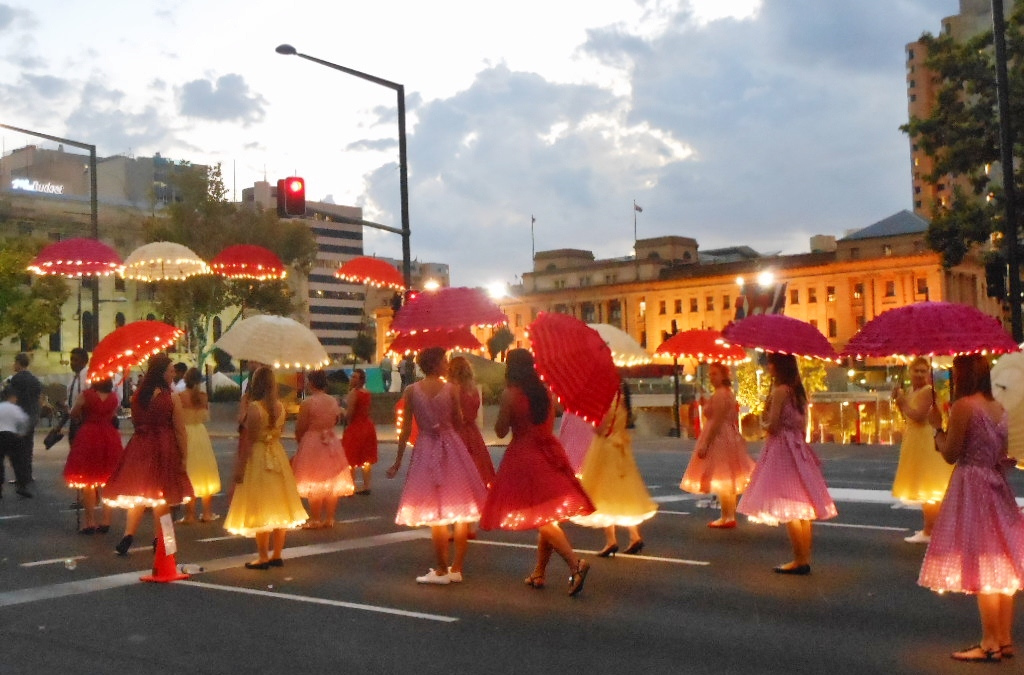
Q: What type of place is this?
A: It is a street.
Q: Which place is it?
A: It is a street.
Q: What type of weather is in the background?
A: It is cloudy.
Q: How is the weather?
A: It is cloudy.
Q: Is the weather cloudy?
A: Yes, it is cloudy.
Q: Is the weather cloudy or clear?
A: It is cloudy.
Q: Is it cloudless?
A: No, it is cloudy.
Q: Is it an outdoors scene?
A: Yes, it is outdoors.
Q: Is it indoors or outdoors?
A: It is outdoors.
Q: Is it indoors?
A: No, it is outdoors.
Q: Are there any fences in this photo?
A: No, there are no fences.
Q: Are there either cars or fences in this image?
A: No, there are no fences or cars.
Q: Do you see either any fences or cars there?
A: No, there are no fences or cars.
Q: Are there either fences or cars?
A: No, there are no fences or cars.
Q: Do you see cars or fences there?
A: No, there are no fences or cars.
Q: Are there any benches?
A: No, there are no benches.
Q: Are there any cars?
A: No, there are no cars.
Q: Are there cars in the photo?
A: No, there are no cars.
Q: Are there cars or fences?
A: No, there are no cars or fences.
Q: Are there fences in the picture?
A: No, there are no fences.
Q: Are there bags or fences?
A: No, there are no fences or bags.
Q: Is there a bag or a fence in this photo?
A: No, there are no fences or bags.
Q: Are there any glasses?
A: No, there are no glasses.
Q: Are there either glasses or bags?
A: No, there are no glasses or bags.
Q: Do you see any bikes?
A: No, there are no bikes.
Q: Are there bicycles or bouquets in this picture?
A: No, there are no bicycles or bouquets.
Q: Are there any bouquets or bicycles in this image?
A: No, there are no bicycles or bouquets.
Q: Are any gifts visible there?
A: No, there are no gifts.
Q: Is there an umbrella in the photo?
A: Yes, there is an umbrella.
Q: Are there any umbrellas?
A: Yes, there is an umbrella.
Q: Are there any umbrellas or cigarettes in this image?
A: Yes, there is an umbrella.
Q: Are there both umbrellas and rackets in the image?
A: No, there is an umbrella but no rackets.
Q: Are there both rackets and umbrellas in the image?
A: No, there is an umbrella but no rackets.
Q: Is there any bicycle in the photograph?
A: No, there are no bicycles.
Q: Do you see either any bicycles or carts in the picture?
A: No, there are no bicycles or carts.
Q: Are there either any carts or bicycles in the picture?
A: No, there are no bicycles or carts.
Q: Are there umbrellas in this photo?
A: Yes, there is an umbrella.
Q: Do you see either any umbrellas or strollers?
A: Yes, there is an umbrella.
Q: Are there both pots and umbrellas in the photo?
A: No, there is an umbrella but no pots.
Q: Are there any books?
A: No, there are no books.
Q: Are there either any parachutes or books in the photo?
A: No, there are no books or parachutes.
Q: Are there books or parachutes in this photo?
A: No, there are no books or parachutes.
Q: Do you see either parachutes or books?
A: No, there are no books or parachutes.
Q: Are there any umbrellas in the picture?
A: Yes, there is an umbrella.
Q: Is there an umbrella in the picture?
A: Yes, there is an umbrella.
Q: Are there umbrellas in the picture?
A: Yes, there is an umbrella.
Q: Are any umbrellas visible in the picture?
A: Yes, there is an umbrella.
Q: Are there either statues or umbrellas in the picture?
A: Yes, there is an umbrella.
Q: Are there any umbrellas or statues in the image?
A: Yes, there is an umbrella.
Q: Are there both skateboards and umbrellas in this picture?
A: No, there is an umbrella but no skateboards.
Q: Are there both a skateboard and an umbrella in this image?
A: No, there is an umbrella but no skateboards.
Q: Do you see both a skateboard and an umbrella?
A: No, there is an umbrella but no skateboards.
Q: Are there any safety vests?
A: No, there are no safety vests.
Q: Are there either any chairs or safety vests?
A: No, there are no safety vests or chairs.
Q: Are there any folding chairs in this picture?
A: No, there are no folding chairs.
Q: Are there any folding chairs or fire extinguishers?
A: No, there are no folding chairs or fire extinguishers.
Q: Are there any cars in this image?
A: No, there are no cars.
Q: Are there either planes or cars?
A: No, there are no cars or planes.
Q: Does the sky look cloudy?
A: Yes, the sky is cloudy.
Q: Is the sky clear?
A: No, the sky is cloudy.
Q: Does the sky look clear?
A: No, the sky is cloudy.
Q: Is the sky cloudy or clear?
A: The sky is cloudy.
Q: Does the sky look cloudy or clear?
A: The sky is cloudy.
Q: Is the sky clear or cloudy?
A: The sky is cloudy.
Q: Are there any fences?
A: No, there are no fences.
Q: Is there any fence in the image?
A: No, there are no fences.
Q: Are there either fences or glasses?
A: No, there are no fences or glasses.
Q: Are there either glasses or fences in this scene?
A: No, there are no fences or glasses.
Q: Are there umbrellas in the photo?
A: Yes, there is an umbrella.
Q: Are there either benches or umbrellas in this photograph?
A: Yes, there is an umbrella.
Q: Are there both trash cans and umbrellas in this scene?
A: No, there is an umbrella but no trash cans.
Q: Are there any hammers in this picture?
A: No, there are no hammers.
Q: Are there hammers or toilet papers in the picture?
A: No, there are no hammers or toilet papers.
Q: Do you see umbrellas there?
A: Yes, there are umbrellas.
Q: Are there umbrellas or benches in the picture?
A: Yes, there are umbrellas.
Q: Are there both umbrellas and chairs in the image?
A: No, there are umbrellas but no chairs.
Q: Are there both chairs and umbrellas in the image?
A: No, there are umbrellas but no chairs.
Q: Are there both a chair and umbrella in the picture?
A: No, there are umbrellas but no chairs.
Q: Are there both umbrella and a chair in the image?
A: No, there are umbrellas but no chairs.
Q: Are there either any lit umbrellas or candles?
A: Yes, there are lit umbrellas.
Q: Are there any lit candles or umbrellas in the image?
A: Yes, there are lit umbrellas.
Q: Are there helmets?
A: No, there are no helmets.